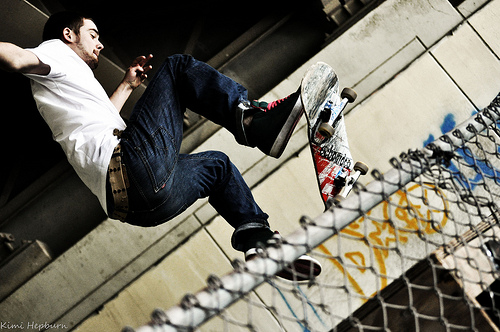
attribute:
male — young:
[1, 9, 306, 279]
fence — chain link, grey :
[121, 96, 498, 331]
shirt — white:
[32, 37, 133, 217]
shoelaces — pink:
[262, 98, 292, 112]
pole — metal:
[322, 106, 485, 236]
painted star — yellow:
[365, 217, 412, 253]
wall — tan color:
[25, 0, 497, 298]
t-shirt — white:
[10, 31, 127, 215]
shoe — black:
[241, 84, 309, 159]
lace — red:
[262, 96, 290, 110]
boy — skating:
[3, 2, 361, 264]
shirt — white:
[18, 69, 153, 174]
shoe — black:
[236, 84, 326, 170]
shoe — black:
[229, 230, 336, 287]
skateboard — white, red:
[297, 60, 363, 214]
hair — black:
[40, 13, 93, 44]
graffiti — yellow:
[291, 186, 466, 293]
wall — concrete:
[212, 147, 484, 325]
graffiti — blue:
[414, 119, 496, 170]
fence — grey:
[314, 212, 474, 314]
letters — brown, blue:
[317, 111, 497, 302]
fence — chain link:
[267, 230, 469, 278]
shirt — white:
[17, 35, 128, 221]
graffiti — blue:
[433, 115, 492, 193]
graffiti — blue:
[415, 106, 497, 197]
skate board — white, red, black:
[294, 64, 364, 205]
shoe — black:
[176, 70, 373, 164]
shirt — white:
[24, 35, 125, 217]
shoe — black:
[251, 72, 361, 179]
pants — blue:
[107, 51, 269, 223]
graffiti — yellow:
[328, 157, 499, 282]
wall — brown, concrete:
[4, 3, 498, 330]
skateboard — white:
[301, 61, 368, 210]